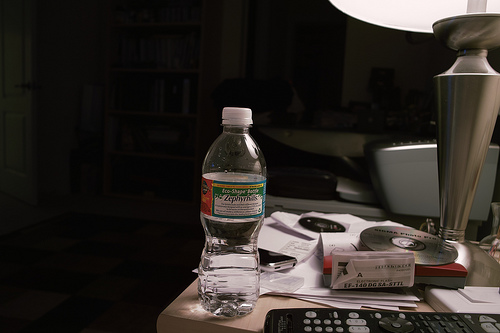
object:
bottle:
[198, 106, 268, 320]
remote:
[261, 307, 499, 332]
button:
[342, 318, 369, 326]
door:
[0, 5, 41, 208]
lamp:
[325, 0, 499, 288]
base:
[431, 12, 500, 288]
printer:
[363, 138, 500, 242]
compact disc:
[358, 225, 458, 267]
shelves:
[98, 1, 219, 208]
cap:
[219, 106, 254, 126]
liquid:
[197, 217, 261, 319]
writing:
[321, 250, 415, 290]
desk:
[155, 210, 500, 331]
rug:
[49, 230, 163, 284]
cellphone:
[255, 247, 298, 273]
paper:
[257, 211, 421, 312]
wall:
[54, 0, 499, 106]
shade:
[327, 0, 500, 35]